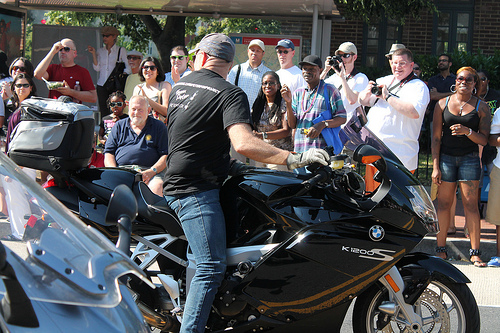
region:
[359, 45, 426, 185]
smiling man in white shirt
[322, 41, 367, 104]
man with camera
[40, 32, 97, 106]
man in maroon shirt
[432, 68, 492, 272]
woman in black tank top and denim shorts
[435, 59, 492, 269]
woman is standing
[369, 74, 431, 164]
shirt is white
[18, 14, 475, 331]
man on motorcycle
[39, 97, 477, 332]
motorcycle is black and orange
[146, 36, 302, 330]
man's head is turned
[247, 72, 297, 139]
short woman in crowd of people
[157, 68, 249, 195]
a black shirt on a man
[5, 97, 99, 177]
a zippered bag on the back of a motorcycle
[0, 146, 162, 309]
the windshield of a motorcycle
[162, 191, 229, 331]
jeans on a man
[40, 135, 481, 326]
a black motorcycle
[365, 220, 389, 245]
the BMW symbol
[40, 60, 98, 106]
a red shirt on a man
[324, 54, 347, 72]
a camera in a man's hands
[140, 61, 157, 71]
sunglasses on a woman's face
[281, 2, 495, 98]
a brick building behind a group of people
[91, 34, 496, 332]
Man on a motorcycle.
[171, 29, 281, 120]
Man wearing a hat.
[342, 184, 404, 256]
Logo on the motorcycle.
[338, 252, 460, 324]
Wheel on the bike.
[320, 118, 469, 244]
Windshield on the bike.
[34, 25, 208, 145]
People in the crowd.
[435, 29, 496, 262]
Woman in a tank top.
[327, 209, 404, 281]
BMW logo on the bike.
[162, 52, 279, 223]
Man with black shirt.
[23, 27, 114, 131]
Man in a red shirt.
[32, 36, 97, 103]
Man in a red shirt holding a salad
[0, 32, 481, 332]
Man on a motorcycle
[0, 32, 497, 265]
Crowd of people observing and taking pictures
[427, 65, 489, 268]
Woman standing and smiling on the side of the road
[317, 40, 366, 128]
Man in a white hat taking pictures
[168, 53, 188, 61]
Lime green color sunglasses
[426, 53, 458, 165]
Man standing behind the crowd with his arms crossed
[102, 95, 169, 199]
Elder man sitting down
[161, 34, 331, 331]
Man in gray baseball cap and black shirt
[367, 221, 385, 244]
BMW symbol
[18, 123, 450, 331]
black BMW motorcycle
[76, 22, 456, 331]
man on a motorcycle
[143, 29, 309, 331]
man wearing a black shirt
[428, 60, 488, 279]
woman wearing a black tank top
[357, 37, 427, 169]
man taking a photograph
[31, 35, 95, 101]
man wearing a red shirt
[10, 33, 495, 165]
crowd on side of road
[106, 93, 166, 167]
man with a white beard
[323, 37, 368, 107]
man taking a photo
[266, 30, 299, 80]
man wearing a blue baseball cap